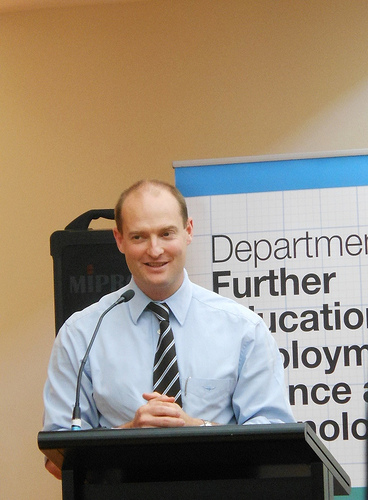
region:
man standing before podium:
[29, 172, 350, 497]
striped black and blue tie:
[138, 300, 192, 425]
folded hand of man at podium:
[100, 374, 214, 430]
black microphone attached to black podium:
[57, 279, 143, 432]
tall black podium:
[26, 417, 355, 499]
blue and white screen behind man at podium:
[169, 145, 366, 498]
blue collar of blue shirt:
[119, 267, 209, 329]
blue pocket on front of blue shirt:
[178, 370, 234, 417]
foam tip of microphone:
[116, 285, 139, 306]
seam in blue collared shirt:
[192, 295, 261, 338]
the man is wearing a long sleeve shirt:
[46, 273, 292, 432]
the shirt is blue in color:
[35, 269, 294, 422]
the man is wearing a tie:
[146, 300, 179, 423]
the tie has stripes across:
[145, 299, 188, 424]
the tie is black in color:
[146, 303, 185, 420]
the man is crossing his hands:
[121, 391, 187, 432]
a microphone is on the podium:
[64, 290, 147, 438]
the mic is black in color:
[64, 288, 133, 432]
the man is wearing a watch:
[197, 417, 216, 431]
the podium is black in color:
[37, 420, 350, 498]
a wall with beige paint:
[33, 17, 226, 118]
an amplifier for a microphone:
[30, 142, 114, 296]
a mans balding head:
[108, 178, 193, 225]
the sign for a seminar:
[198, 132, 366, 368]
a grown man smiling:
[97, 188, 188, 296]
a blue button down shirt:
[53, 267, 273, 444]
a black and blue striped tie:
[135, 301, 194, 398]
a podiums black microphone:
[91, 281, 154, 435]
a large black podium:
[51, 404, 340, 492]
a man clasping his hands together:
[128, 351, 196, 435]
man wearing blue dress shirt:
[39, 161, 295, 424]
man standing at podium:
[37, 159, 355, 495]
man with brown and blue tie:
[40, 169, 301, 424]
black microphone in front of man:
[58, 280, 134, 422]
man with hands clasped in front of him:
[50, 172, 293, 426]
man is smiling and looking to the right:
[39, 173, 295, 422]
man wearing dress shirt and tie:
[40, 159, 296, 423]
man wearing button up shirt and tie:
[38, 169, 287, 427]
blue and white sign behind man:
[170, 160, 367, 481]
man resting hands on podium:
[47, 180, 304, 438]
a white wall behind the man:
[6, 28, 366, 136]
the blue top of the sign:
[179, 167, 364, 200]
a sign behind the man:
[176, 164, 360, 451]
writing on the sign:
[212, 233, 363, 438]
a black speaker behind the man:
[48, 212, 113, 284]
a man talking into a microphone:
[63, 219, 314, 470]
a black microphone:
[71, 287, 143, 415]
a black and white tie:
[150, 305, 184, 398]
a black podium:
[41, 413, 361, 482]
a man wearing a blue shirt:
[44, 191, 296, 455]